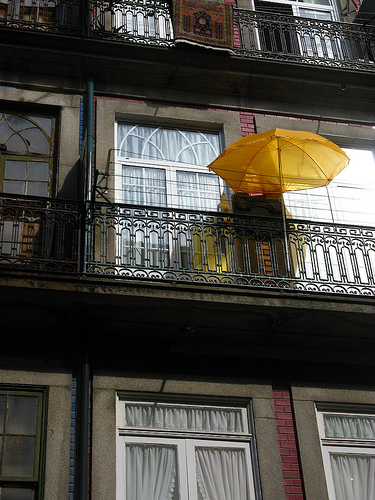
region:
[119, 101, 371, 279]
umbrella is opened up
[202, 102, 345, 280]
umbrella has long pole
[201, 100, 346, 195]
umbrella is golden yellow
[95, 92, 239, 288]
white curtain is hanging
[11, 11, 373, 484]
multiple windows line building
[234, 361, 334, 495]
building has red brick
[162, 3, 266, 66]
rug hanging from rail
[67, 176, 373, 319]
railing has design pattern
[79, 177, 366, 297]
guard rail is black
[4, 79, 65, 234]
window seals are rusted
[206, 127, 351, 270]
Large yellow umbrella on a patio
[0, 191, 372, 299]
Decorative detail on patio railing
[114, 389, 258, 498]
White curtains in a window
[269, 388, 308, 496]
Red brick on a building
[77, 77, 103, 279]
Pipe on the side of a building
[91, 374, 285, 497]
Concrete around a window frame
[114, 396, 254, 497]
Small horizontal window above two vertical windows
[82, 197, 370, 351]
Concrete patio on a building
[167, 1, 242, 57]
Rug hanging over a patio railing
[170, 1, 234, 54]
White fringe on a rug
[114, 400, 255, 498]
White curtains inside window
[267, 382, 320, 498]
Red bricks on building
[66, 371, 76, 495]
Blue bricks on building wall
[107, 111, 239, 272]
Window on the side of a building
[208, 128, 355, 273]
A yellow umbrella open on a balcony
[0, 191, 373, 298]
Metal patterned rail around balcony.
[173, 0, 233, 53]
Carpet hanging off rail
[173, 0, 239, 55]
Oriental rug hanging to dry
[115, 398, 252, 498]
White wooden windowsills around glass windows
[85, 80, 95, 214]
Blue pole on buildings railing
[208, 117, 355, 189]
yellow umbrella on terrace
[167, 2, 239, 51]
rug hanging from railing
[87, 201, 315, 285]
railing area in front of window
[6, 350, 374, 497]
a story underneath a story in a building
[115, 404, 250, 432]
rectangular window in a building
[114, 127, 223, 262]
a window with curtains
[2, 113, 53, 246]
a window without curtains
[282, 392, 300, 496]
red brick between windows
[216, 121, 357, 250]
yellow umbrella on balcony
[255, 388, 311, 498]
red bricks on wall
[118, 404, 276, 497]
white frame around doors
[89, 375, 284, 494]
grey stone frame outside doors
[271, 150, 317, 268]
umbrella on steel pole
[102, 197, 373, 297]
black railing on balcony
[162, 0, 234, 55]
brown rug on railing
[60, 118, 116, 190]
blue pole outside door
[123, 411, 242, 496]
white curtains inside doors